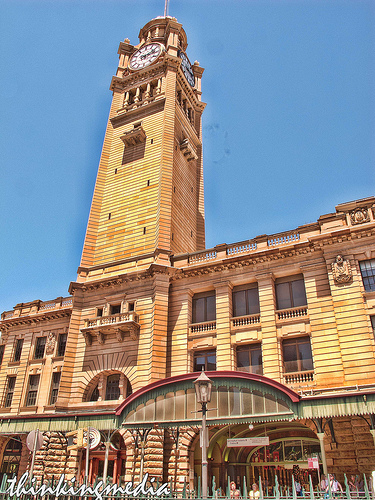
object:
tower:
[52, 0, 207, 411]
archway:
[186, 418, 326, 498]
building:
[0, 2, 374, 496]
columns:
[26, 420, 237, 487]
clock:
[130, 44, 161, 69]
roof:
[136, 14, 185, 32]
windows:
[192, 289, 217, 324]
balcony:
[82, 311, 140, 330]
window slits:
[128, 89, 136, 112]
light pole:
[193, 368, 214, 500]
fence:
[0, 473, 375, 499]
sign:
[226, 437, 270, 449]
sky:
[202, 0, 375, 250]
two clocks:
[180, 55, 194, 87]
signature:
[6, 472, 172, 500]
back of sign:
[26, 429, 43, 452]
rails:
[120, 312, 131, 322]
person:
[249, 482, 261, 500]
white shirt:
[249, 491, 259, 498]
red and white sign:
[308, 456, 320, 469]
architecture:
[18, 346, 154, 413]